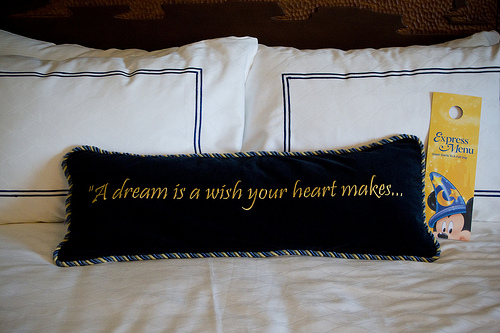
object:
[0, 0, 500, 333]
bed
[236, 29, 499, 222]
pillow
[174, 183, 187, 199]
words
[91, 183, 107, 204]
letter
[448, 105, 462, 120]
hole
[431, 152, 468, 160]
phrase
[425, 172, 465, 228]
hat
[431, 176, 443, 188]
print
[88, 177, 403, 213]
lettering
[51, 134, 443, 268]
bag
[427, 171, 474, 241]
mickey mouse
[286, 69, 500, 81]
trim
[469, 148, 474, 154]
letters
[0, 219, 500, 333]
blanket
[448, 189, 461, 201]
stars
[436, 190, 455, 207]
moons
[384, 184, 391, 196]
letters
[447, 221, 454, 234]
eyes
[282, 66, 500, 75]
lines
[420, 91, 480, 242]
door hanger